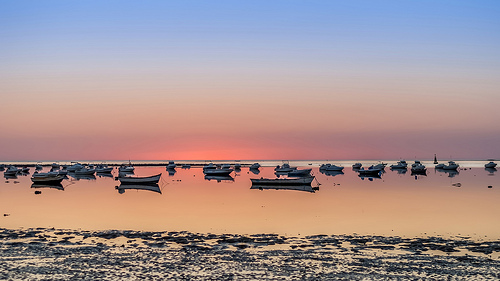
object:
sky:
[122, 15, 166, 47]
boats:
[117, 173, 166, 187]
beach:
[112, 229, 404, 245]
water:
[267, 210, 344, 217]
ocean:
[250, 201, 285, 216]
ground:
[137, 240, 173, 270]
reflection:
[393, 215, 424, 230]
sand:
[150, 256, 175, 267]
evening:
[228, 144, 346, 161]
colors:
[336, 82, 352, 140]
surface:
[80, 210, 105, 221]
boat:
[30, 174, 66, 185]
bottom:
[247, 181, 315, 186]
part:
[315, 177, 321, 184]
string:
[315, 178, 323, 188]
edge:
[368, 170, 373, 171]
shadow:
[249, 184, 316, 194]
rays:
[205, 103, 231, 135]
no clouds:
[409, 20, 444, 46]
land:
[354, 237, 405, 250]